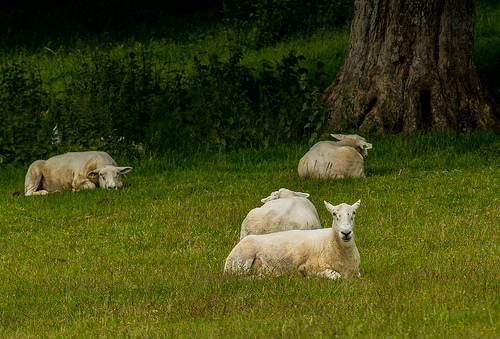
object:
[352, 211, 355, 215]
eye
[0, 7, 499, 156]
shrubs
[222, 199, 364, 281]
animal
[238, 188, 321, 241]
animal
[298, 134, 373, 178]
animal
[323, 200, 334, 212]
ear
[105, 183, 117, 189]
mouth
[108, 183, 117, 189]
nose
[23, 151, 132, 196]
animal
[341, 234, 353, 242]
mouth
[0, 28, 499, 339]
field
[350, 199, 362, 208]
ear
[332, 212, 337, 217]
eyes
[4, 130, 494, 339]
patch